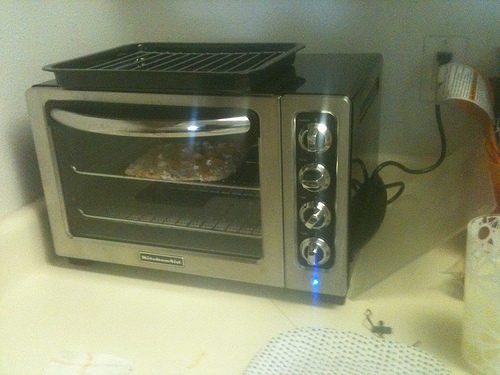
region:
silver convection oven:
[43, 43, 393, 283]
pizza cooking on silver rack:
[122, 123, 248, 192]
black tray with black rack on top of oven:
[51, 25, 310, 85]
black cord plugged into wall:
[373, 3, 497, 214]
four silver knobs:
[298, 118, 357, 269]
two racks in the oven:
[63, 135, 264, 230]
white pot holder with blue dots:
[243, 319, 445, 371]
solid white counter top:
[26, 295, 211, 352]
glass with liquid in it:
[456, 210, 498, 368]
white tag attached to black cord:
[429, 56, 497, 116]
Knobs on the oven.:
[268, 102, 359, 280]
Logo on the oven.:
[127, 236, 203, 283]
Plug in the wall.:
[407, 20, 482, 90]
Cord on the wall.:
[372, 89, 441, 200]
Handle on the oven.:
[42, 92, 307, 169]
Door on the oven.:
[45, 101, 377, 308]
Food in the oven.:
[101, 122, 246, 197]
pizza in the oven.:
[134, 131, 265, 207]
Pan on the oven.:
[44, 31, 302, 98]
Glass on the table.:
[447, 187, 497, 300]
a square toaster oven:
[3, 26, 378, 317]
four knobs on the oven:
[282, 107, 339, 286]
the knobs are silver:
[289, 97, 334, 277]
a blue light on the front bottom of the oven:
[295, 270, 326, 299]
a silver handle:
[22, 91, 257, 149]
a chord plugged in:
[365, 42, 452, 214]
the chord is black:
[392, 35, 452, 215]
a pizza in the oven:
[99, 115, 240, 194]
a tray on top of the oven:
[44, 3, 298, 95]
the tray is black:
[55, 21, 305, 85]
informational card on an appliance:
[433, 60, 496, 120]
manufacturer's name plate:
[135, 245, 190, 275]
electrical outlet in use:
[417, 25, 469, 105]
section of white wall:
[0, 111, 21, 202]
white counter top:
[6, 281, 223, 361]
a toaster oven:
[20, 75, 360, 300]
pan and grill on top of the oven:
[50, 20, 315, 85]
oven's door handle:
[45, 95, 265, 140]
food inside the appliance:
[110, 135, 245, 180]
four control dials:
[285, 103, 340, 284]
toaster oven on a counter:
[23, 25, 381, 317]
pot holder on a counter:
[256, 318, 442, 371]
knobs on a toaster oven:
[299, 124, 350, 279]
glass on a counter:
[448, 198, 494, 365]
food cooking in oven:
[126, 146, 233, 189]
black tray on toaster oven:
[32, 27, 319, 79]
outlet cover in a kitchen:
[422, 26, 476, 119]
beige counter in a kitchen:
[13, 284, 163, 340]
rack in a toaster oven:
[83, 202, 255, 258]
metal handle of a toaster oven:
[57, 98, 259, 144]